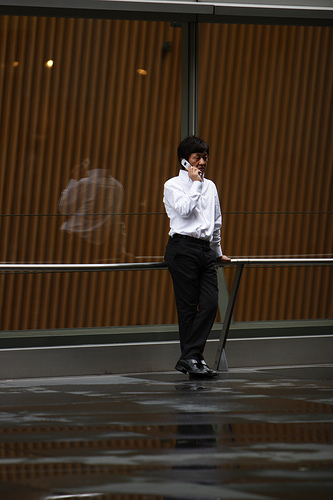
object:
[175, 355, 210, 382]
shoes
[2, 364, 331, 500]
water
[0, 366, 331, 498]
road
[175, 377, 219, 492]
reflection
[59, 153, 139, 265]
reflection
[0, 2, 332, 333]
window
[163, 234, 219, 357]
pants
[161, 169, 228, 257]
shirt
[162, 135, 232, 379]
man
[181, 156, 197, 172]
phone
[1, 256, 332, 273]
rail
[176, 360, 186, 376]
heel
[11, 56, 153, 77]
reflection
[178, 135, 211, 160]
hair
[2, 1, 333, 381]
building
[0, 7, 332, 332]
wall